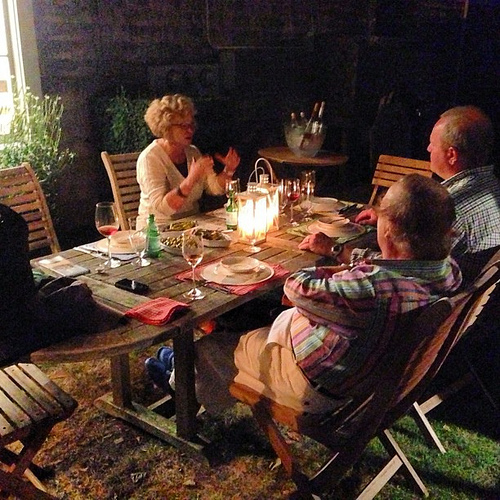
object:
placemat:
[199, 250, 276, 287]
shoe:
[144, 355, 171, 398]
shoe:
[156, 346, 174, 372]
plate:
[200, 255, 275, 286]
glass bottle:
[145, 213, 161, 258]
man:
[298, 103, 498, 270]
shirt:
[437, 162, 500, 284]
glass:
[238, 181, 266, 246]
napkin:
[123, 297, 188, 336]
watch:
[328, 241, 344, 258]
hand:
[215, 146, 242, 169]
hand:
[191, 155, 215, 181]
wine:
[187, 251, 199, 265]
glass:
[182, 229, 207, 301]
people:
[135, 93, 242, 232]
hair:
[143, 93, 199, 137]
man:
[144, 173, 457, 478]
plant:
[0, 72, 77, 226]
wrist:
[327, 236, 347, 261]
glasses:
[168, 121, 199, 131]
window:
[0, 0, 50, 159]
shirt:
[283, 248, 463, 402]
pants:
[169, 327, 353, 417]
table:
[29, 180, 380, 462]